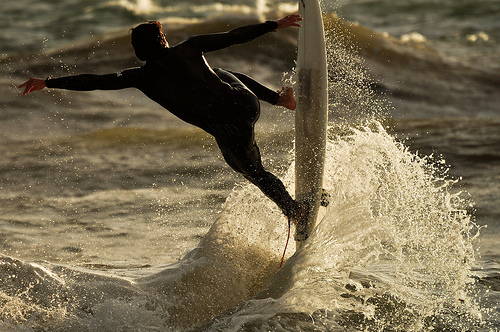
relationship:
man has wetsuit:
[18, 11, 309, 237] [111, 45, 280, 188]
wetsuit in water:
[111, 45, 280, 188] [83, 218, 223, 274]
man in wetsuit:
[107, 53, 253, 131] [111, 45, 280, 188]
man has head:
[107, 53, 253, 131] [130, 18, 198, 57]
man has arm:
[107, 53, 253, 131] [50, 65, 115, 109]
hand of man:
[21, 66, 50, 105] [107, 53, 253, 131]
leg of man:
[209, 134, 303, 232] [107, 53, 253, 131]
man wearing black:
[18, 11, 309, 237] [176, 87, 235, 134]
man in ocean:
[107, 53, 253, 131] [56, 31, 399, 250]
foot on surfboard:
[267, 85, 302, 113] [292, 25, 328, 215]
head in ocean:
[130, 18, 198, 57] [56, 31, 399, 250]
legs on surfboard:
[228, 65, 299, 116] [292, 25, 328, 215]